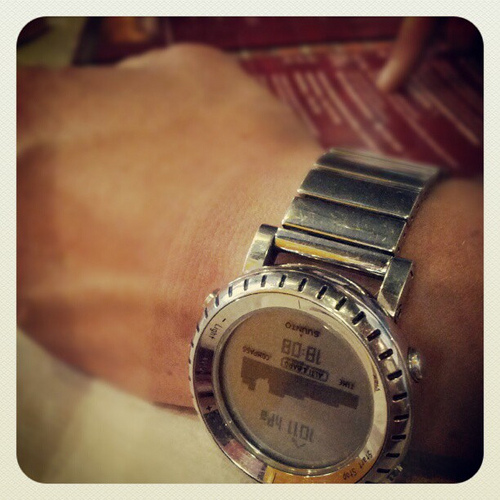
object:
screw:
[406, 346, 424, 384]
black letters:
[281, 337, 322, 365]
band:
[270, 141, 437, 280]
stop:
[342, 467, 357, 480]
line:
[242, 278, 250, 291]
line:
[260, 274, 267, 288]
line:
[277, 272, 288, 288]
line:
[297, 277, 309, 294]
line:
[314, 284, 330, 300]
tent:
[335, 462, 367, 484]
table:
[20, 45, 482, 486]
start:
[358, 450, 373, 469]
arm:
[273, 178, 484, 474]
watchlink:
[298, 164, 424, 219]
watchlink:
[312, 146, 441, 187]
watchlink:
[276, 195, 406, 256]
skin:
[18, 44, 483, 475]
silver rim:
[259, 265, 387, 344]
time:
[286, 420, 315, 443]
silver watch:
[185, 147, 445, 483]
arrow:
[291, 436, 305, 449]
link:
[281, 190, 408, 254]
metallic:
[243, 143, 446, 320]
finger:
[371, 17, 431, 95]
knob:
[407, 343, 428, 384]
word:
[208, 323, 223, 340]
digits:
[281, 338, 322, 365]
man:
[18, 44, 485, 461]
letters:
[240, 321, 355, 391]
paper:
[243, 44, 484, 184]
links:
[296, 149, 421, 221]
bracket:
[240, 144, 441, 322]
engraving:
[189, 264, 425, 486]